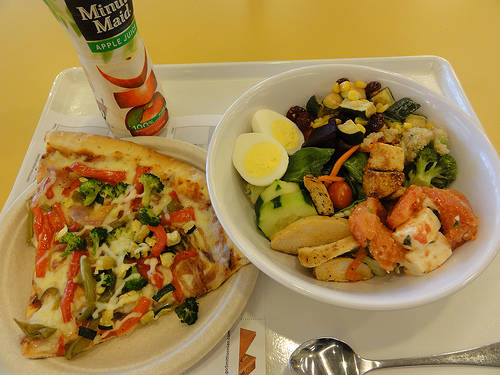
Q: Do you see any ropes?
A: No, there are no ropes.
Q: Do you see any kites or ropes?
A: No, there are no ropes or kites.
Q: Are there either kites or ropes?
A: No, there are no ropes or kites.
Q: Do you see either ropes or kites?
A: No, there are no ropes or kites.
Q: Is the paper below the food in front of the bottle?
A: Yes, the paper is below the food.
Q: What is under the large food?
A: The paper is under the food.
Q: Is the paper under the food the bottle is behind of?
A: Yes, the paper is under the food.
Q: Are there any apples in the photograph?
A: Yes, there are apples.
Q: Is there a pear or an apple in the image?
A: Yes, there are apples.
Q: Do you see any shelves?
A: No, there are no shelves.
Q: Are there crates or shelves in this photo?
A: No, there are no shelves or crates.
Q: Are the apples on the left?
A: Yes, the apples are on the left of the image.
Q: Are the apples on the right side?
A: No, the apples are on the left of the image.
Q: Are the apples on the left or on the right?
A: The apples are on the left of the image.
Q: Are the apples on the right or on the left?
A: The apples are on the left of the image.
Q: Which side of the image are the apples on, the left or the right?
A: The apples are on the left of the image.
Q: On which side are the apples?
A: The apples are on the left of the image.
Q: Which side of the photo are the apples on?
A: The apples are on the left of the image.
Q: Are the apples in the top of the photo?
A: Yes, the apples are in the top of the image.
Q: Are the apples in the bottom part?
A: No, the apples are in the top of the image.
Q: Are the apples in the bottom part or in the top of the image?
A: The apples are in the top of the image.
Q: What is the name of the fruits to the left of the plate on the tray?
A: The fruits are apples.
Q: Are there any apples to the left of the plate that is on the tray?
A: Yes, there are apples to the left of the plate.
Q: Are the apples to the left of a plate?
A: Yes, the apples are to the left of a plate.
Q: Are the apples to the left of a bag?
A: No, the apples are to the left of a plate.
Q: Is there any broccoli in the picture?
A: Yes, there is broccoli.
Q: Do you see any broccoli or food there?
A: Yes, there is broccoli.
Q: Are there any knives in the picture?
A: No, there are no knives.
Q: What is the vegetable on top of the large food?
A: The vegetable is broccoli.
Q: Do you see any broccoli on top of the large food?
A: Yes, there is broccoli on top of the food.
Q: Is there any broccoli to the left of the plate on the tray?
A: Yes, there is broccoli to the left of the plate.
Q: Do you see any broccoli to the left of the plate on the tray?
A: Yes, there is broccoli to the left of the plate.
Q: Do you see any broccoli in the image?
A: Yes, there is broccoli.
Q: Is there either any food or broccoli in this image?
A: Yes, there is broccoli.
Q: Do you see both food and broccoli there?
A: Yes, there are both broccoli and food.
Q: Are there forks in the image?
A: No, there are no forks.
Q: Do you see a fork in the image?
A: No, there are no forks.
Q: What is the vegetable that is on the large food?
A: The vegetable is broccoli.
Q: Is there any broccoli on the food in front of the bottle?
A: Yes, there is broccoli on the food.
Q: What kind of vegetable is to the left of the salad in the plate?
A: The vegetable is broccoli.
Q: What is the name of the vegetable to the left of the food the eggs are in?
A: The vegetable is broccoli.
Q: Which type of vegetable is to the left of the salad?
A: The vegetable is broccoli.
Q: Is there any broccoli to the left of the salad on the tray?
A: Yes, there is broccoli to the left of the salad.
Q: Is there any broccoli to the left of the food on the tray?
A: Yes, there is broccoli to the left of the salad.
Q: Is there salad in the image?
A: Yes, there is salad.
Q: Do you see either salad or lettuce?
A: Yes, there is salad.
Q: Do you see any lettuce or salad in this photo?
A: Yes, there is salad.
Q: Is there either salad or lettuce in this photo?
A: Yes, there is salad.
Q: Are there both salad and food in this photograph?
A: Yes, there are both salad and food.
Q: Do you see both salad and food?
A: Yes, there are both salad and food.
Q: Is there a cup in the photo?
A: No, there are no cups.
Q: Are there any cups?
A: No, there are no cups.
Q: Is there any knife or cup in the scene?
A: No, there are no cups or knives.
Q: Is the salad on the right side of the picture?
A: Yes, the salad is on the right of the image.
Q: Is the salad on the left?
A: No, the salad is on the right of the image.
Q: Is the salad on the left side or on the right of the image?
A: The salad is on the right of the image.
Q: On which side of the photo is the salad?
A: The salad is on the right of the image.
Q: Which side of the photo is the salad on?
A: The salad is on the right of the image.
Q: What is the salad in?
A: The salad is in the plate.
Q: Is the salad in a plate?
A: Yes, the salad is in a plate.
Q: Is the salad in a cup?
A: No, the salad is in a plate.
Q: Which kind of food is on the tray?
A: The food is salad.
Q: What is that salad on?
A: The salad is on the tray.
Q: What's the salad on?
A: The salad is on the tray.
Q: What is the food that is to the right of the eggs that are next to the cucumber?
A: The food is salad.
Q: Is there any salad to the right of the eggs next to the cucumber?
A: Yes, there is salad to the right of the eggs.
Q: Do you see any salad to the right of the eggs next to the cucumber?
A: Yes, there is salad to the right of the eggs.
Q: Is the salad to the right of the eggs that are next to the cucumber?
A: Yes, the salad is to the right of the eggs.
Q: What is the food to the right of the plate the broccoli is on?
A: The food is salad.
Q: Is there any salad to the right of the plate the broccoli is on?
A: Yes, there is salad to the right of the plate.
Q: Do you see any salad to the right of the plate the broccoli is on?
A: Yes, there is salad to the right of the plate.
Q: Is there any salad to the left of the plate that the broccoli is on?
A: No, the salad is to the right of the plate.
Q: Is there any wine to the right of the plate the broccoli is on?
A: No, there is salad to the right of the plate.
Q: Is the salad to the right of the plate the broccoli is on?
A: Yes, the salad is to the right of the plate.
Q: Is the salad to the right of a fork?
A: No, the salad is to the right of the plate.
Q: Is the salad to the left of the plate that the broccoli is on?
A: No, the salad is to the right of the plate.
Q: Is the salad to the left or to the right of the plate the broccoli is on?
A: The salad is to the right of the plate.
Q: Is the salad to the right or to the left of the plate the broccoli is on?
A: The salad is to the right of the plate.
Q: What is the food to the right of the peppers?
A: The food is salad.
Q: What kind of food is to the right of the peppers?
A: The food is salad.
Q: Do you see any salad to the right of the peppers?
A: Yes, there is salad to the right of the peppers.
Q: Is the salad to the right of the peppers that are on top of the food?
A: Yes, the salad is to the right of the peppers.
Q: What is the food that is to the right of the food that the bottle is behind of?
A: The food is salad.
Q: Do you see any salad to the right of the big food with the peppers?
A: Yes, there is salad to the right of the food.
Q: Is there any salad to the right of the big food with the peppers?
A: Yes, there is salad to the right of the food.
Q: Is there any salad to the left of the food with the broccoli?
A: No, the salad is to the right of the food.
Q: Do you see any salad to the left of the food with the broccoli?
A: No, the salad is to the right of the food.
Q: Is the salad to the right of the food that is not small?
A: Yes, the salad is to the right of the food.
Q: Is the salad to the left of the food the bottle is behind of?
A: No, the salad is to the right of the food.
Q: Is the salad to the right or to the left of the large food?
A: The salad is to the right of the food.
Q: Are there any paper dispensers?
A: No, there are no paper dispensers.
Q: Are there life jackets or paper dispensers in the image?
A: No, there are no paper dispensers or life jackets.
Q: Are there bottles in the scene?
A: Yes, there is a bottle.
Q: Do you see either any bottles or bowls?
A: Yes, there is a bottle.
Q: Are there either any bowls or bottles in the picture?
A: Yes, there is a bottle.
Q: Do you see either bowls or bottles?
A: Yes, there is a bottle.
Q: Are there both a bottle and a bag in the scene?
A: No, there is a bottle but no bags.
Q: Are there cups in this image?
A: No, there are no cups.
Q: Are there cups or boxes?
A: No, there are no cups or boxes.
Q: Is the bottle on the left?
A: Yes, the bottle is on the left of the image.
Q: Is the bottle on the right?
A: No, the bottle is on the left of the image.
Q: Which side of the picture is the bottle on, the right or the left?
A: The bottle is on the left of the image.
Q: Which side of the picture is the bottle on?
A: The bottle is on the left of the image.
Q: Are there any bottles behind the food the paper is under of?
A: Yes, there is a bottle behind the food.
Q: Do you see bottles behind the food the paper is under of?
A: Yes, there is a bottle behind the food.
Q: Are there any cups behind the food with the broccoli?
A: No, there is a bottle behind the food.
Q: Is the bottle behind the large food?
A: Yes, the bottle is behind the food.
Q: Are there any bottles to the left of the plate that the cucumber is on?
A: Yes, there is a bottle to the left of the plate.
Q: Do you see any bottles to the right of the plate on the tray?
A: No, the bottle is to the left of the plate.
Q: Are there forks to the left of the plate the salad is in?
A: No, there is a bottle to the left of the plate.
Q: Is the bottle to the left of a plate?
A: Yes, the bottle is to the left of a plate.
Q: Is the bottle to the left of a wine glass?
A: No, the bottle is to the left of a plate.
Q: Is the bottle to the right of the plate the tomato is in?
A: No, the bottle is to the left of the plate.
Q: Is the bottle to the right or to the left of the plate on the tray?
A: The bottle is to the left of the plate.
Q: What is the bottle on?
A: The bottle is on the tray.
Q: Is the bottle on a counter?
A: No, the bottle is on the tray.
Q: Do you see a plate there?
A: Yes, there is a plate.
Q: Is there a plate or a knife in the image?
A: Yes, there is a plate.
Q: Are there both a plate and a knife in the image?
A: No, there is a plate but no knives.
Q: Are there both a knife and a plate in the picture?
A: No, there is a plate but no knives.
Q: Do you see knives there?
A: No, there are no knives.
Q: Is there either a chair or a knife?
A: No, there are no knives or chairs.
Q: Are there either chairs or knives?
A: No, there are no knives or chairs.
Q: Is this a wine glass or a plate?
A: This is a plate.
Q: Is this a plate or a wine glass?
A: This is a plate.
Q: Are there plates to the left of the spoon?
A: Yes, there is a plate to the left of the spoon.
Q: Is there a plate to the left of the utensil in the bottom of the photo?
A: Yes, there is a plate to the left of the spoon.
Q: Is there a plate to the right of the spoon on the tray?
A: No, the plate is to the left of the spoon.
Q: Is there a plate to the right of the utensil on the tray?
A: No, the plate is to the left of the spoon.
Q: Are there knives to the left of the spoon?
A: No, there is a plate to the left of the spoon.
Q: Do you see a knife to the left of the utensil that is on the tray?
A: No, there is a plate to the left of the spoon.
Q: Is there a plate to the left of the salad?
A: Yes, there is a plate to the left of the salad.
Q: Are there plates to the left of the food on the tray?
A: Yes, there is a plate to the left of the salad.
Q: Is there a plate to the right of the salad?
A: No, the plate is to the left of the salad.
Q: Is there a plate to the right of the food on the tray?
A: No, the plate is to the left of the salad.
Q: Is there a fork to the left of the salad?
A: No, there is a plate to the left of the salad.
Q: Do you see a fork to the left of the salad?
A: No, there is a plate to the left of the salad.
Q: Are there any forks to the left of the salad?
A: No, there is a plate to the left of the salad.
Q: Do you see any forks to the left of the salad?
A: No, there is a plate to the left of the salad.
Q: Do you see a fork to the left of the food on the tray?
A: No, there is a plate to the left of the salad.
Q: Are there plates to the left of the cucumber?
A: Yes, there is a plate to the left of the cucumber.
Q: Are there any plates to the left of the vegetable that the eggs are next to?
A: Yes, there is a plate to the left of the cucumber.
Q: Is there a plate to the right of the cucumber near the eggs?
A: No, the plate is to the left of the cucumber.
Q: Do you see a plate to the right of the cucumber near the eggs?
A: No, the plate is to the left of the cucumber.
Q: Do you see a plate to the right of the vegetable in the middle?
A: No, the plate is to the left of the cucumber.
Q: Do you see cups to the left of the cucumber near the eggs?
A: No, there is a plate to the left of the cucumber.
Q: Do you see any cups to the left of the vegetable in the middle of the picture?
A: No, there is a plate to the left of the cucumber.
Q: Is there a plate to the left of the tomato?
A: Yes, there is a plate to the left of the tomato.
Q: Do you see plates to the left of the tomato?
A: Yes, there is a plate to the left of the tomato.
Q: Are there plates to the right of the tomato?
A: No, the plate is to the left of the tomato.